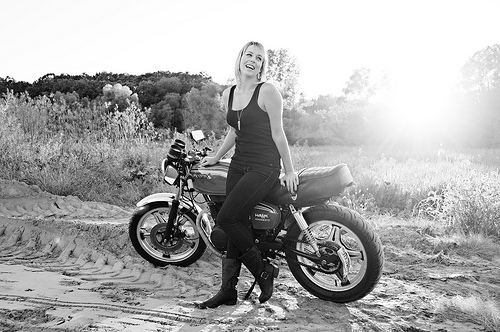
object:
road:
[4, 185, 498, 330]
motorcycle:
[127, 128, 384, 303]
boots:
[238, 242, 282, 304]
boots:
[192, 259, 243, 310]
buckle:
[260, 271, 270, 280]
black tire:
[285, 201, 383, 303]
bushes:
[1, 82, 160, 193]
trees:
[454, 44, 497, 141]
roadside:
[0, 144, 500, 217]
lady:
[193, 39, 302, 312]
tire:
[131, 195, 208, 268]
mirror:
[163, 164, 180, 186]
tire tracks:
[3, 224, 193, 300]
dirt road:
[0, 179, 492, 329]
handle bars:
[185, 173, 198, 194]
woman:
[194, 38, 301, 309]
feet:
[192, 282, 239, 309]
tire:
[282, 204, 385, 304]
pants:
[216, 162, 281, 259]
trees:
[133, 70, 207, 132]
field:
[0, 144, 498, 332]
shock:
[287, 202, 320, 260]